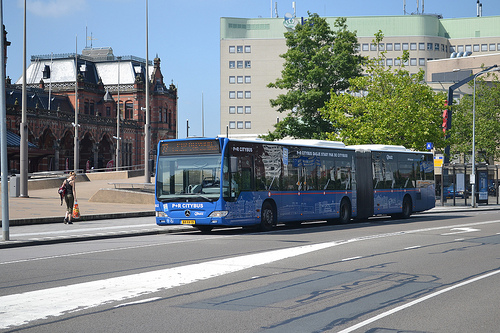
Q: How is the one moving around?
A: Walking.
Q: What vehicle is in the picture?
A: A bus.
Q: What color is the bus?
A: Blue.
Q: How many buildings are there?
A: Two.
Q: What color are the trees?
A: Green.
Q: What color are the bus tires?
A: Black.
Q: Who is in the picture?
A: A woman.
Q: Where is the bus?
A: On the street.